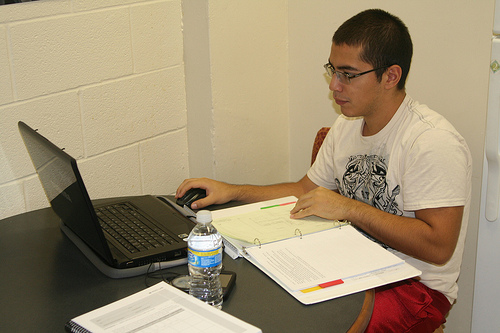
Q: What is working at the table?
A: The man.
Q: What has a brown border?
A: Round, black table.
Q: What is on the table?
A: Black laptop computer.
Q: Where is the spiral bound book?
A: On the table.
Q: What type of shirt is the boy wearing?
A: A t-shirt.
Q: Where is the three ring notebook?
A: On the table.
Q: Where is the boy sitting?
A: At the table.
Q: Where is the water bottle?
A: On the table.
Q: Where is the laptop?
A: On the table.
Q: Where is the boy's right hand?
A: On the computer mouse.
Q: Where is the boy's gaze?
A: On the laptop.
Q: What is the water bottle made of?
A: Plastic.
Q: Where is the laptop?
A: Table.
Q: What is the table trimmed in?
A: Wood.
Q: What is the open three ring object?
A: Notebook.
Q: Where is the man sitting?
A: Table.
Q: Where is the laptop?
A: Table.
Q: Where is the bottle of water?
A: Table.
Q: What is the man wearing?
A: White shirt.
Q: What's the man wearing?
A: Red shorts.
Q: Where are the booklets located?
A: Table.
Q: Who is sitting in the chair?
A: Young man.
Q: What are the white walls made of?
A: White brick.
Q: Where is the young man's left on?
A: A loose leaf note book.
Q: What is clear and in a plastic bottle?
A: Water.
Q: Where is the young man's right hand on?
A: Computer mouse.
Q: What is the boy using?
A: A laptop.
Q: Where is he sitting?
A: A desk.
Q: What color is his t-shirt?
A: White.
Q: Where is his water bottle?
A: His left.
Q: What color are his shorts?
A: Red.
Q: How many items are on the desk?
A: 5.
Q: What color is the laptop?
A: Black.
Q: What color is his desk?
A: Gray.